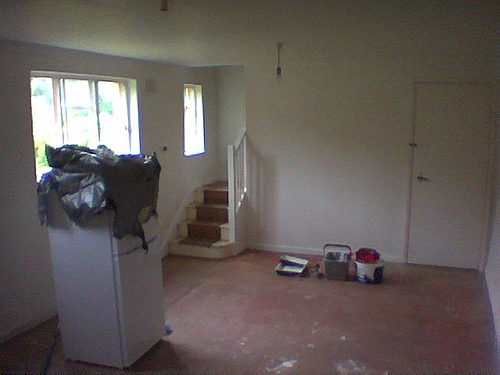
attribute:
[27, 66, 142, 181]
frame — white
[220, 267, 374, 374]
floor — reddish , orange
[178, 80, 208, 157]
window — small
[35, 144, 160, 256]
tarp — grey, plastic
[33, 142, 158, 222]
garbage bags — black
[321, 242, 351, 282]
bucket — grey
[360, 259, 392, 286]
bucket — large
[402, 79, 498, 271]
door — white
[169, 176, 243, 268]
steps — white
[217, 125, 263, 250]
railing — white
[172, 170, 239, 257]
stairs — short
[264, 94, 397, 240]
wall — white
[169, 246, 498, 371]
floor — red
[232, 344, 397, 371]
paint — white 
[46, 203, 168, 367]
fridge — white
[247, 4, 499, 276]
wall — white, bare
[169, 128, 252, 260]
staircase — wood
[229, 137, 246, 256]
rail — white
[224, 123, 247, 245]
railing — white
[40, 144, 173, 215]
cover — black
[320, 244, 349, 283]
pail — grey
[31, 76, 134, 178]
window — bright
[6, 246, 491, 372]
floor — cement